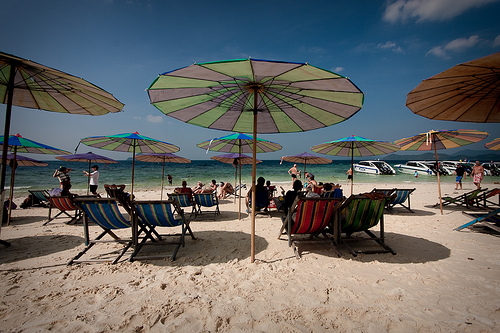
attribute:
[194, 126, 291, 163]
umbrella — red, yellow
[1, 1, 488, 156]
sky — blue, dark blue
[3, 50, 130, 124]
umbrella — red, yellow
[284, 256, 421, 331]
beach — sandy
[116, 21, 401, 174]
umbrella — open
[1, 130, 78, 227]
umbrella — open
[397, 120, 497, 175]
umbrella — big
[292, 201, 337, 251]
chair — red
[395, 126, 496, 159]
umbrella — red, yellow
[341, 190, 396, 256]
chair — green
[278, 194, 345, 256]
chair — red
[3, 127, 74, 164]
umbrella — red, yellow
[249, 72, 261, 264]
pole — wooden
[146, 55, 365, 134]
unbrella — open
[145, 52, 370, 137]
umbrella — open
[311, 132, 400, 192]
umbrella — open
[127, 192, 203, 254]
chair — blue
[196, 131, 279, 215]
umbrella — big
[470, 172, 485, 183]
shorts — pink, white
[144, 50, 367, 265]
umbrella — red, yellow, open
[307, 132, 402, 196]
umbrella — big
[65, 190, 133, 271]
beach chair — blue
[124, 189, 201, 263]
beach chair — blue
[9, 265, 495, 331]
sand — soft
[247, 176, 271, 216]
man — sitting